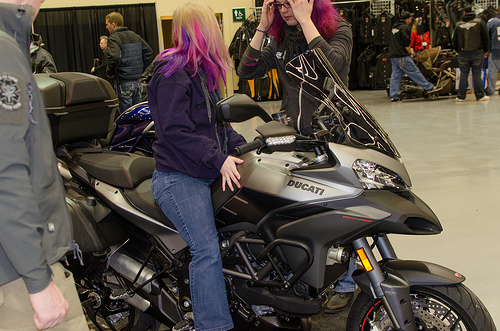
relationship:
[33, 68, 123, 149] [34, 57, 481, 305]
helmet box on back of cycle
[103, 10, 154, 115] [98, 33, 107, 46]
man drinking coffee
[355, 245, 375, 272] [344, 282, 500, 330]
street sign above tire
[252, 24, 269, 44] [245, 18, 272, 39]
wristband on arm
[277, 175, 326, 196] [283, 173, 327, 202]
logo for ducati gazelles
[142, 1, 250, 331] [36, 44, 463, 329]
friends looking at bike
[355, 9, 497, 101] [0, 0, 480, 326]
people at motor convention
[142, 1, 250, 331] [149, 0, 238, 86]
friends with hair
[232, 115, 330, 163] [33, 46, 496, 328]
handle bar on motorcycle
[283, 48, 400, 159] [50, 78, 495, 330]
bike windshield on bike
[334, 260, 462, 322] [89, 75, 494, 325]
tire on motorcycle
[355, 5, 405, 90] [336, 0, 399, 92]
shirts hanging on rack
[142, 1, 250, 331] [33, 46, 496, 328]
friends sitting on motorcycle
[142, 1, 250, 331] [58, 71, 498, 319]
friends sitting on motorcycle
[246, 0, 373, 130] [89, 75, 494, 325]
friends checking out motorcycle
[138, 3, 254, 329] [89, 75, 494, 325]
friends checking out motorcycle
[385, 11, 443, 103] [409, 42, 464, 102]
man pushing stroller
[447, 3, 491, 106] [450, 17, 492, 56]
man standing in jacket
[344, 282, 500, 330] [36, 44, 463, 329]
tire of bike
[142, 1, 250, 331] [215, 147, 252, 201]
friends left hand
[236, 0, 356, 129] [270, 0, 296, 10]
friends has glasses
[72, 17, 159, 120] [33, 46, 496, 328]
man looking at motorcycle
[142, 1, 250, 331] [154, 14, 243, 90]
friends with pink hair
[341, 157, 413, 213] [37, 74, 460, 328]
headlight on a motorcycle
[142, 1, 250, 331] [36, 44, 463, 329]
friends on bike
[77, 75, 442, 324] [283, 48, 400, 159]
bike has a bike windshield